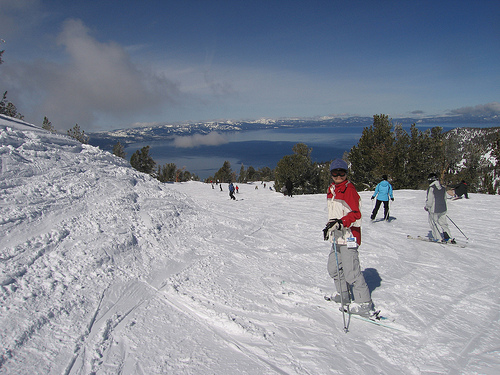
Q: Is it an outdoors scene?
A: Yes, it is outdoors.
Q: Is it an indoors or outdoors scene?
A: It is outdoors.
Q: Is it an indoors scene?
A: No, it is outdoors.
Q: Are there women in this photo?
A: Yes, there is a woman.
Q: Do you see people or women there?
A: Yes, there is a woman.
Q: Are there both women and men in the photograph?
A: Yes, there are both a woman and a man.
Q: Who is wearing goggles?
A: The woman is wearing goggles.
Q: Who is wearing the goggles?
A: The woman is wearing goggles.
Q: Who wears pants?
A: The woman wears pants.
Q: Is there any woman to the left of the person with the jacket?
A: Yes, there is a woman to the left of the person.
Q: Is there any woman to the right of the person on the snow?
A: No, the woman is to the left of the person.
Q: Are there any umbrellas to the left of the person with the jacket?
A: No, there is a woman to the left of the person.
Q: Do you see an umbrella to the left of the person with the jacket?
A: No, there is a woman to the left of the person.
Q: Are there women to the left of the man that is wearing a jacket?
A: Yes, there is a woman to the left of the man.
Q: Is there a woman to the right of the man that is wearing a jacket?
A: No, the woman is to the left of the man.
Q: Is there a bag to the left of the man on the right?
A: No, there is a woman to the left of the man.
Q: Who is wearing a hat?
A: The woman is wearing a hat.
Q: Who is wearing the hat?
A: The woman is wearing a hat.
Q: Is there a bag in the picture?
A: No, there are no bags.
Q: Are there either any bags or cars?
A: No, there are no bags or cars.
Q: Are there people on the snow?
A: Yes, there is a person on the snow.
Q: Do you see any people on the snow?
A: Yes, there is a person on the snow.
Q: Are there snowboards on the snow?
A: No, there is a person on the snow.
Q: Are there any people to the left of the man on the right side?
A: Yes, there is a person to the left of the man.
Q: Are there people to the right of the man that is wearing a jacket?
A: No, the person is to the left of the man.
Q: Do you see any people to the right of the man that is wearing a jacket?
A: No, the person is to the left of the man.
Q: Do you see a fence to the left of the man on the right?
A: No, there is a person to the left of the man.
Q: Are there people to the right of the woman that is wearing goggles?
A: Yes, there is a person to the right of the woman.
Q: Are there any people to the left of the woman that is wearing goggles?
A: No, the person is to the right of the woman.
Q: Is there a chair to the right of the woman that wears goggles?
A: No, there is a person to the right of the woman.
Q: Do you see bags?
A: No, there are no bags.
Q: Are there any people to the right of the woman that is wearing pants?
A: Yes, there is a person to the right of the woman.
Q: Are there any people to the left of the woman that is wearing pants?
A: No, the person is to the right of the woman.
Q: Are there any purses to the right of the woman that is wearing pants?
A: No, there is a person to the right of the woman.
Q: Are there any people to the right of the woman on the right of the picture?
A: Yes, there is a person to the right of the woman.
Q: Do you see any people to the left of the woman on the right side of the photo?
A: No, the person is to the right of the woman.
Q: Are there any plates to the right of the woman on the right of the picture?
A: No, there is a person to the right of the woman.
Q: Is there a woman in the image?
A: Yes, there is a woman.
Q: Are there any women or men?
A: Yes, there is a woman.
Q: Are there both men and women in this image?
A: Yes, there are both a woman and a man.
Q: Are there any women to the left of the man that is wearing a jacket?
A: Yes, there is a woman to the left of the man.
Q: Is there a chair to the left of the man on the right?
A: No, there is a woman to the left of the man.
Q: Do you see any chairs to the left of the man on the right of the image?
A: No, there is a woman to the left of the man.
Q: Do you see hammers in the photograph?
A: No, there are no hammers.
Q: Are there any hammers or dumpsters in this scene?
A: No, there are no hammers or dumpsters.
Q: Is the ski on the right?
A: Yes, the ski is on the right of the image.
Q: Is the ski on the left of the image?
A: No, the ski is on the right of the image.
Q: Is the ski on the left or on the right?
A: The ski is on the right of the image.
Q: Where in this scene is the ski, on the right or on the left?
A: The ski is on the right of the image.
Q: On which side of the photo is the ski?
A: The ski is on the right of the image.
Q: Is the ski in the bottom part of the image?
A: Yes, the ski is in the bottom of the image.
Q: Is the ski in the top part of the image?
A: No, the ski is in the bottom of the image.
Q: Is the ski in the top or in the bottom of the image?
A: The ski is in the bottom of the image.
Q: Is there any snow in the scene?
A: Yes, there is snow.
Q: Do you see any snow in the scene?
A: Yes, there is snow.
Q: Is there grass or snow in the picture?
A: Yes, there is snow.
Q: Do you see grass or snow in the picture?
A: Yes, there is snow.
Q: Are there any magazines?
A: No, there are no magazines.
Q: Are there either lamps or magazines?
A: No, there are no magazines or lamps.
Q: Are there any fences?
A: No, there are no fences.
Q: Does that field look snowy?
A: Yes, the field is snowy.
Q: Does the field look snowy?
A: Yes, the field is snowy.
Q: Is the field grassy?
A: No, the field is snowy.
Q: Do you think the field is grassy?
A: No, the field is snowy.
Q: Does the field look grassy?
A: No, the field is snowy.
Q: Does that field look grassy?
A: No, the field is snowy.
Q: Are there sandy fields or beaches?
A: No, there is a field but it is snowy.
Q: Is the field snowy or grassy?
A: The field is snowy.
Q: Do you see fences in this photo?
A: No, there are no fences.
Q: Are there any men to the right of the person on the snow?
A: Yes, there is a man to the right of the person.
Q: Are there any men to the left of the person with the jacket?
A: No, the man is to the right of the person.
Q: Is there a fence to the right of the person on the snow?
A: No, there is a man to the right of the person.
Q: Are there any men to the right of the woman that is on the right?
A: Yes, there is a man to the right of the woman.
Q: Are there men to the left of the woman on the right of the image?
A: No, the man is to the right of the woman.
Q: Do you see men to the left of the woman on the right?
A: No, the man is to the right of the woman.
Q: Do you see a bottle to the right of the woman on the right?
A: No, there is a man to the right of the woman.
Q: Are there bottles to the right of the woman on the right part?
A: No, there is a man to the right of the woman.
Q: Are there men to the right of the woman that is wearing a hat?
A: Yes, there is a man to the right of the woman.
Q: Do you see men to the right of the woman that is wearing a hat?
A: Yes, there is a man to the right of the woman.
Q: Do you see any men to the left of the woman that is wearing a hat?
A: No, the man is to the right of the woman.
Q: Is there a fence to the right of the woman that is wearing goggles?
A: No, there is a man to the right of the woman.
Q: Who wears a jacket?
A: The man wears a jacket.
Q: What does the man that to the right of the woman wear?
A: The man wears a jacket.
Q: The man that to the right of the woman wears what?
A: The man wears a jacket.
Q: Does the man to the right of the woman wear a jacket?
A: Yes, the man wears a jacket.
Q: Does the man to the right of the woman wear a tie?
A: No, the man wears a jacket.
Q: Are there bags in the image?
A: No, there are no bags.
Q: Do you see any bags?
A: No, there are no bags.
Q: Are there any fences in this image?
A: No, there are no fences.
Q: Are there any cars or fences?
A: No, there are no fences or cars.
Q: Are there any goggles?
A: Yes, there are goggles.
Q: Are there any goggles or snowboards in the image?
A: Yes, there are goggles.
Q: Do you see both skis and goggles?
A: Yes, there are both goggles and skis.